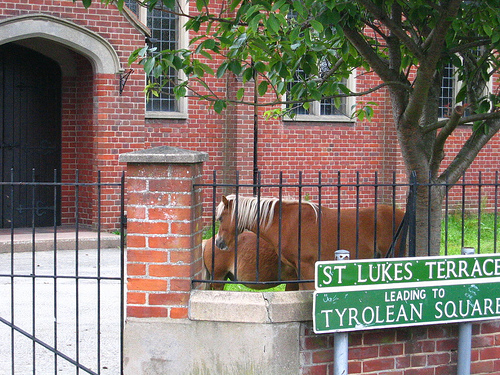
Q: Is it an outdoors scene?
A: Yes, it is outdoors.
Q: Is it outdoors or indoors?
A: It is outdoors.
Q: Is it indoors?
A: No, it is outdoors.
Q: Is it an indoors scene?
A: No, it is outdoors.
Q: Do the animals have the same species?
A: Yes, all the animals are horses.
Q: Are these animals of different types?
A: No, all the animals are horses.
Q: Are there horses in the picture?
A: Yes, there is a horse.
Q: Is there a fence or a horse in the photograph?
A: Yes, there is a horse.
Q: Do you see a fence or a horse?
A: Yes, there is a horse.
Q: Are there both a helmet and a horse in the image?
A: No, there is a horse but no helmets.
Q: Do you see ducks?
A: No, there are no ducks.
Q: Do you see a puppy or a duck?
A: No, there are no ducks or puppies.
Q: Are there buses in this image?
A: No, there are no buses.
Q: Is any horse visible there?
A: Yes, there are horses.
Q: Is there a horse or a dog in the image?
A: Yes, there are horses.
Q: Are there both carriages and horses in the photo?
A: No, there are horses but no carriages.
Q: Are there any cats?
A: No, there are no cats.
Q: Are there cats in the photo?
A: No, there are no cats.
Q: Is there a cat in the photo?
A: No, there are no cats.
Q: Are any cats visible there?
A: No, there are no cats.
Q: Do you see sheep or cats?
A: No, there are no cats or sheep.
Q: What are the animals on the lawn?
A: The animals are horses.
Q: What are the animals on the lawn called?
A: The animals are horses.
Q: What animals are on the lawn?
A: The animals are horses.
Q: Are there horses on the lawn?
A: Yes, there are horses on the lawn.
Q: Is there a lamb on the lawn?
A: No, there are horses on the lawn.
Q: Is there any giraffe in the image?
A: No, there are no giraffes.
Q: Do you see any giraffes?
A: No, there are no giraffes.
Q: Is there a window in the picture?
A: Yes, there is a window.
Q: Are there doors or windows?
A: Yes, there is a window.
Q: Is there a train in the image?
A: No, there are no trains.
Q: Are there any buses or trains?
A: No, there are no trains or buses.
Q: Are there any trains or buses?
A: No, there are no trains or buses.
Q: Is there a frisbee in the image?
A: Yes, there is a frisbee.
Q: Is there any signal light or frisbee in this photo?
A: Yes, there is a frisbee.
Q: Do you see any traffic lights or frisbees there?
A: Yes, there is a frisbee.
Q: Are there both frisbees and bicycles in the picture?
A: No, there is a frisbee but no bicycles.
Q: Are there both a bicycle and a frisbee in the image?
A: No, there is a frisbee but no bicycles.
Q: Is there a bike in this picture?
A: No, there are no bikes.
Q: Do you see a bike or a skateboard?
A: No, there are no bikes or skateboards.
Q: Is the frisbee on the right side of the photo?
A: Yes, the frisbee is on the right of the image.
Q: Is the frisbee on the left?
A: No, the frisbee is on the right of the image.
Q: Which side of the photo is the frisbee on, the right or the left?
A: The frisbee is on the right of the image.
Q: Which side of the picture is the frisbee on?
A: The frisbee is on the right of the image.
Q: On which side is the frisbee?
A: The frisbee is on the right of the image.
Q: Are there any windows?
A: Yes, there is a window.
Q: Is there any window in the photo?
A: Yes, there is a window.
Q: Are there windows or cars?
A: Yes, there is a window.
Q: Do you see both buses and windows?
A: No, there is a window but no buses.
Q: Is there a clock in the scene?
A: No, there are no clocks.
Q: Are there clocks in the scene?
A: No, there are no clocks.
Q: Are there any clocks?
A: No, there are no clocks.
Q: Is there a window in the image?
A: Yes, there is a window.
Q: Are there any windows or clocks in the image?
A: Yes, there is a window.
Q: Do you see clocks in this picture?
A: No, there are no clocks.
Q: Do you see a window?
A: Yes, there is a window.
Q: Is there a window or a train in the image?
A: Yes, there is a window.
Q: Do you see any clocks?
A: No, there are no clocks.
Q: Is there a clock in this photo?
A: No, there are no clocks.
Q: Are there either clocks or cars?
A: No, there are no clocks or cars.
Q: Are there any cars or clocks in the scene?
A: No, there are no clocks or cars.